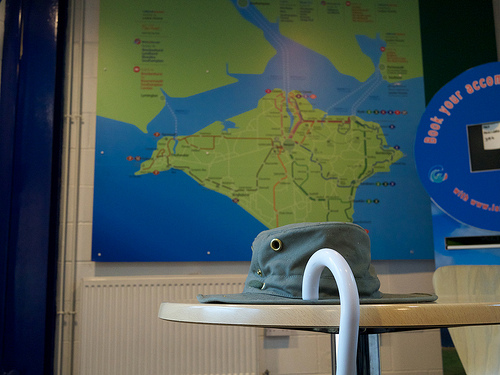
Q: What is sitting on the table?
A: A hat.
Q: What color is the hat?
A: Blue.